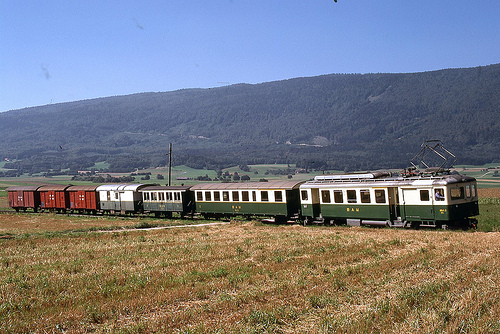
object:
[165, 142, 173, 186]
pole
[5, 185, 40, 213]
train car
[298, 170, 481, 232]
train car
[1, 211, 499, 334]
field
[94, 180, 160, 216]
train car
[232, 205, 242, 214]
sign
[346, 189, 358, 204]
window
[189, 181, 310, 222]
train car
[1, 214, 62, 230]
dirt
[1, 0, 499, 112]
sky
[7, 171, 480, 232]
train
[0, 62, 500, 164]
hill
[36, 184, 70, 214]
train car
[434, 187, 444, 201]
man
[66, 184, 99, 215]
train car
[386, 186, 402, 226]
entrance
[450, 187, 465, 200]
window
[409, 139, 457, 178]
object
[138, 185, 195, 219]
train car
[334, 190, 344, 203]
window